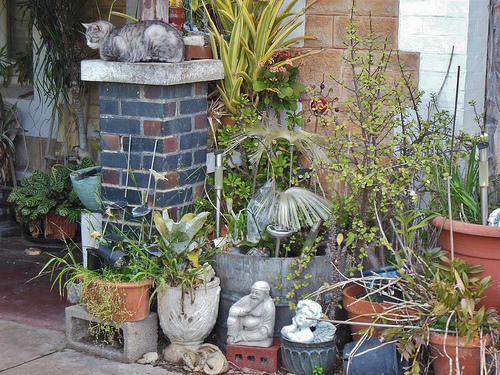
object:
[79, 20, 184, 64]
cat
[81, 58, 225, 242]
pillar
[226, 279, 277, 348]
graden statue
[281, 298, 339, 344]
graden statue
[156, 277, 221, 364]
vase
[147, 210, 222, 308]
plant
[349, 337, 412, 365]
flower pot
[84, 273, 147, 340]
plant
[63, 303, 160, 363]
cement stone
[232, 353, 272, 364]
brick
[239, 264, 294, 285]
stone structure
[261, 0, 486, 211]
wall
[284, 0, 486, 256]
building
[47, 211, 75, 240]
clay pot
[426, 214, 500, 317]
large flowerpot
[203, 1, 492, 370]
garden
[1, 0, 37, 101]
window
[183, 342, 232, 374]
resting dragon